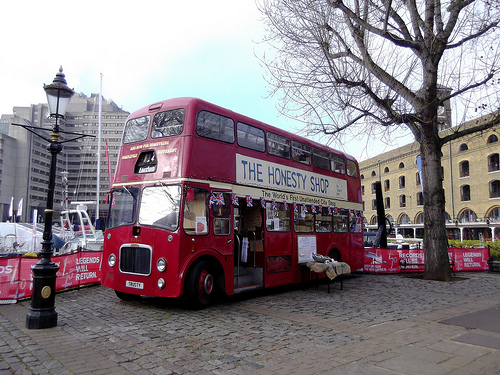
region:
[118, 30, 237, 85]
The sky is blue and white.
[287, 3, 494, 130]
The tree has no leaves.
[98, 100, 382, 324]
A double decker bus.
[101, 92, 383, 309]
The bus is red.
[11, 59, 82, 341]
A lamp post.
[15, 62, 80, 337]
The lamp post is black.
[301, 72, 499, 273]
Buildings are in the background.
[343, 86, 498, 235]
The building is tan.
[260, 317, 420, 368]
The ground is gray and brown.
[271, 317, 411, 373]
The ground is made of blocks.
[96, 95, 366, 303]
the bus is a double decker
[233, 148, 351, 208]
a sign is on the side of the bus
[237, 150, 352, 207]
the sign has a white background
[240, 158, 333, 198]
the lettering is blue in color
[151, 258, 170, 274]
a headlight is in front of the bus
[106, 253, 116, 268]
a headlight is in front of the bus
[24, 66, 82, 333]
the lampost is black in color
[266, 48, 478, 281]
a tree is besides the bus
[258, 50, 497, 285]
the tree is bare without leaves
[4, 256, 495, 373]
the pavement is cobbled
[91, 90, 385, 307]
double-decker bus on a street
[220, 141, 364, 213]
letters on side of double-decker bus says "The Honesty Shop"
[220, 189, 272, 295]
door of bus is wide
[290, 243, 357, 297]
a table in front of bus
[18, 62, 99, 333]
street light in front of bus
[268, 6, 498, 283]
a tree close to bus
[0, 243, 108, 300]
red banner behind the bus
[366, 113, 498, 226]
a yellow building in front of park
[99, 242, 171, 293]
two headlights in front of bus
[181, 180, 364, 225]
British flags on side of bus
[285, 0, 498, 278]
A leafless deciduous tree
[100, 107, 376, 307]
gorgeous double decker bus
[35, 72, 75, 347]
beautiful tall streetlight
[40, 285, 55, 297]
gold detailing of lamp post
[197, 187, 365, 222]
string of Union jack flags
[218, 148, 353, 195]
Honesty shop banner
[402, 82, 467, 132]
gorgeous clock tower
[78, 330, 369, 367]
old fashioned cobble stone street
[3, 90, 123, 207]
tall building with lots of windows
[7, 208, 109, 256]
ships ready to depart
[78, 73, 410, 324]
a red decker bus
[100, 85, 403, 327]
a double decker with flags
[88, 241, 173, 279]
a headlight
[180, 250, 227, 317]
a front wheel of a bus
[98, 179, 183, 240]
a windshield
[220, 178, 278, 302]
a door of a double decker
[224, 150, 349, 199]
a sign on a double decker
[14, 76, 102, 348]
a light post next to the double decker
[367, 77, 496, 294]
a tree without leaves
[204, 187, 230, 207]
a british flag